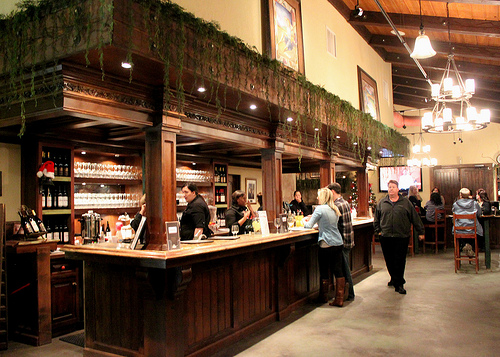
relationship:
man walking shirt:
[363, 164, 430, 300] [375, 197, 421, 239]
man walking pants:
[363, 164, 430, 300] [379, 232, 416, 289]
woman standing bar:
[299, 186, 354, 308] [0, 0, 499, 355]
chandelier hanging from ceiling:
[420, 60, 491, 136] [380, 5, 495, 114]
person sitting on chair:
[453, 185, 484, 265] [451, 210, 478, 272]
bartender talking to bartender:
[176, 181, 211, 242] [127, 189, 148, 243]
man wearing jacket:
[373, 180, 427, 294] [373, 194, 426, 242]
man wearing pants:
[373, 180, 427, 294] [380, 235, 410, 294]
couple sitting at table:
[452, 182, 492, 248] [466, 207, 497, 272]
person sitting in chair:
[451, 184, 483, 256] [454, 211, 481, 271]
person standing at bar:
[328, 179, 357, 304] [59, 210, 378, 355]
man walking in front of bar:
[373, 180, 427, 294] [59, 210, 378, 355]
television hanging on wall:
[378, 162, 423, 192] [371, 106, 498, 248]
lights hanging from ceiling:
[404, 27, 493, 137] [316, 0, 498, 134]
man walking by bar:
[373, 180, 427, 294] [59, 210, 378, 355]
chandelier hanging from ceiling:
[407, 44, 494, 137] [334, 1, 495, 123]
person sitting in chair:
[450, 180, 484, 260] [452, 211, 482, 269]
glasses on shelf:
[78, 160, 142, 203] [69, 145, 147, 214]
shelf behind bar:
[69, 145, 147, 214] [120, 122, 397, 350]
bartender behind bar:
[178, 183, 214, 241] [4, 4, 419, 356]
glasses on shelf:
[73, 161, 140, 177] [73, 175, 143, 185]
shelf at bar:
[73, 175, 143, 185] [0, 0, 499, 355]